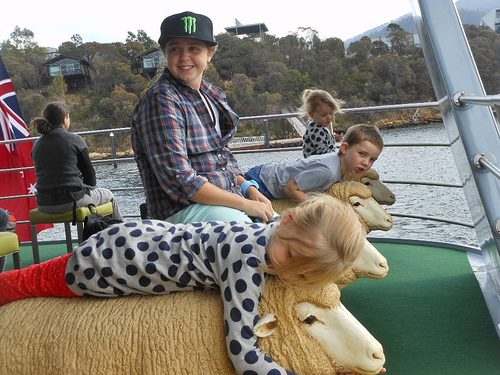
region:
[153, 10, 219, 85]
woman wearing black baseball cap with logo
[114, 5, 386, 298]
woman with three little kids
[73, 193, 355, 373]
blonde girl wearing polka dot shirt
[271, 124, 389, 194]
little boy wearing gray T shirt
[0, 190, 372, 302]
girl wearing red patterned knit pants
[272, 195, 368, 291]
little girl with long blonde hair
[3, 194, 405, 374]
little girl lying on sheep statue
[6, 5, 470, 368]
several people on a boat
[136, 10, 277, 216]
woman wearing dark plaid shirt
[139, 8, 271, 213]
woman wearing blue wristband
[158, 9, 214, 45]
a Monster brand baseball cap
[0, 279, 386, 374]
plastic sheep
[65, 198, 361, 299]
young child in a polka dot shirt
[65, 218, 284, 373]
a long sleeve child's tunic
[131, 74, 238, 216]
button up long sleeve flannel shirt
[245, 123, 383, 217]
a small child laying on a plastic sheep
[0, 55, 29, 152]
flag of the united kingdom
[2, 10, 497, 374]
children playing on a boat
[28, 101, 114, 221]
a woman sitting on a stool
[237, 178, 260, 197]
blue watch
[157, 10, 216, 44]
black cap with green logo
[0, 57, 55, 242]
red, white, and blue hanging flag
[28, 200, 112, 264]
small bench with green cushioned seat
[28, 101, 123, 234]
dark haired woman seated on bench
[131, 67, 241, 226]
plaid button up long sleeve shirt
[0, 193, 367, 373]
young blond girl wearing white top with black polka dots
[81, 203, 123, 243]
black backpack on ground next to seat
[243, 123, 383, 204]
young boy wearing gray t-shirt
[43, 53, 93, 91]
house on tree filled waterfront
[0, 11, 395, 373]
four kids playing on fake sheep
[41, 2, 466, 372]
The people are riding on a boat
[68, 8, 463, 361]
The people are traveling by water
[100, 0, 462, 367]
Some kids are laying on something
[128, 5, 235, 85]
A person is wearing a hat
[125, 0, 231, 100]
A person has a big smile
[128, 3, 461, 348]
The family is crossing the water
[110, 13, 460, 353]
The family is taking a trip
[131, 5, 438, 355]
The family is enjoying the water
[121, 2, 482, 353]
The family is safe on a boat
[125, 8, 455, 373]
The family is enjoying their day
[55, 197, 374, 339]
girl with polka dot shirt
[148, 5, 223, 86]
girl with black ballcap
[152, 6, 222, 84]
black ball cap with green logo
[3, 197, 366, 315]
girl wearing red pants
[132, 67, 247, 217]
plaid button down shirt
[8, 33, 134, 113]
house on a wooded hillside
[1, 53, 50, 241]
red white and blue flag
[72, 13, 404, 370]
children on animal statues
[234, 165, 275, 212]
wrist with wide blue band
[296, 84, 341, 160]
child wearing a white and black shirt